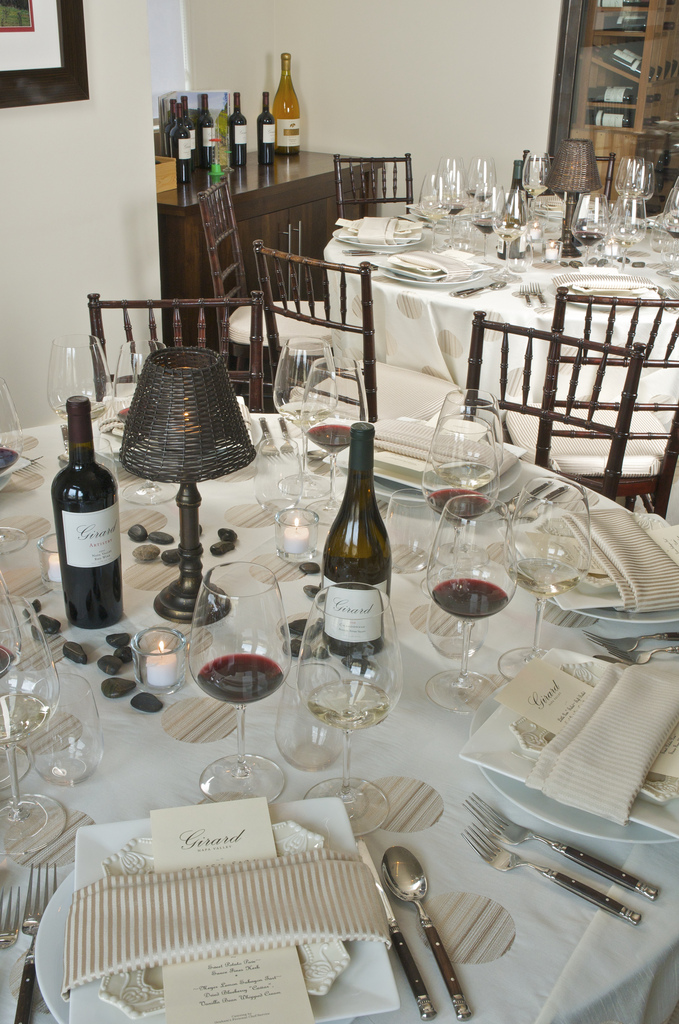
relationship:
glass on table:
[495, 472, 591, 691] [4, 402, 676, 1021]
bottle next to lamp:
[44, 390, 130, 622] [114, 342, 257, 624]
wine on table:
[57, 394, 133, 635] [4, 402, 676, 1021]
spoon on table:
[380, 842, 475, 1022] [4, 402, 676, 1021]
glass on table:
[188, 559, 292, 806] [4, 402, 676, 1021]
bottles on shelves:
[601, 45, 642, 80] [543, 1, 675, 214]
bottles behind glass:
[601, 45, 642, 80] [561, 4, 653, 136]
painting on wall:
[5, 6, 128, 128] [16, 13, 150, 237]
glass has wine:
[186, 558, 292, 808] [196, 655, 286, 701]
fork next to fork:
[457, 817, 648, 930] [462, 787, 659, 905]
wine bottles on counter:
[160, 48, 305, 191] [155, 145, 383, 362]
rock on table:
[128, 690, 163, 713] [4, 402, 676, 1021]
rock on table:
[99, 675, 137, 699] [4, 402, 676, 1021]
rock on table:
[62, 639, 89, 666] [4, 402, 676, 1021]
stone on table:
[130, 540, 163, 564] [4, 402, 676, 1021]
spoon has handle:
[378, 842, 481, 1021] [419, 913, 475, 1021]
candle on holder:
[131, 624, 187, 696] [131, 621, 187, 698]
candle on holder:
[280, 514, 310, 554] [273, 507, 318, 562]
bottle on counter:
[270, 48, 307, 160] [150, 140, 378, 406]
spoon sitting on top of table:
[378, 842, 481, 1021] [4, 402, 676, 1021]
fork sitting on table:
[462, 787, 659, 905] [4, 402, 676, 1021]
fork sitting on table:
[457, 817, 648, 930] [4, 402, 676, 1021]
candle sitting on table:
[144, 636, 178, 689] [4, 402, 676, 1021]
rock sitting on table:
[129, 688, 167, 716] [4, 402, 676, 1021]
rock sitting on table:
[101, 672, 138, 700] [4, 402, 676, 1021]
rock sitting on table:
[60, 639, 92, 663] [4, 402, 676, 1021]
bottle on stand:
[255, 89, 279, 168] [155, 127, 383, 368]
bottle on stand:
[225, 86, 253, 169] [155, 127, 383, 368]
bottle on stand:
[195, 89, 217, 172] [155, 127, 383, 368]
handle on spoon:
[412, 912, 474, 1019] [378, 842, 481, 1021]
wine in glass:
[197, 651, 287, 705] [186, 558, 292, 808]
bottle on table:
[256, 88, 275, 167] [154, 148, 382, 354]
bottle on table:
[227, 89, 249, 170] [154, 148, 382, 354]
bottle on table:
[193, 86, 218, 171] [154, 148, 382, 354]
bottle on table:
[271, 47, 301, 155] [154, 148, 382, 354]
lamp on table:
[114, 342, 257, 624] [4, 402, 676, 1021]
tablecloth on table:
[324, 216, 677, 412] [324, 200, 678, 499]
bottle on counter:
[271, 47, 301, 155] [157, 148, 387, 296]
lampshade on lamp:
[119, 342, 258, 486] [114, 342, 257, 624]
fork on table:
[460, 818, 644, 927] [4, 402, 676, 1021]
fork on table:
[462, 787, 659, 905] [4, 402, 676, 1021]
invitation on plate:
[145, 793, 321, 1022] [66, 795, 401, 1022]